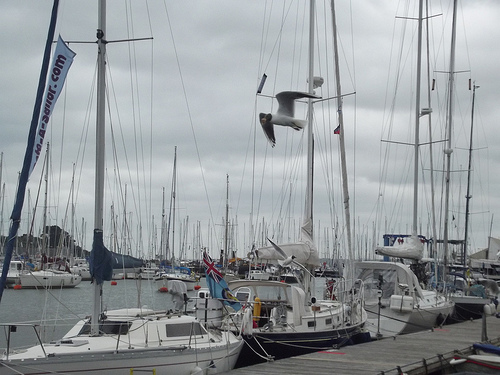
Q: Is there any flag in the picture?
A: Yes, there is a flag.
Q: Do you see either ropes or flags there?
A: Yes, there is a flag.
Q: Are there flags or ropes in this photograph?
A: Yes, there is a flag.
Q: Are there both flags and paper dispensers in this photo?
A: No, there is a flag but no paper dispensers.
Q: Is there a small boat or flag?
A: Yes, there is a small flag.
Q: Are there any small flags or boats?
A: Yes, there is a small flag.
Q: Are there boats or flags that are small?
A: Yes, the flag is small.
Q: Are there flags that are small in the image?
A: Yes, there is a small flag.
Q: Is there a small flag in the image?
A: Yes, there is a small flag.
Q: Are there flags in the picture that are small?
A: Yes, there is a flag that is small.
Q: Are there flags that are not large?
A: Yes, there is a small flag.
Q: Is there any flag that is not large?
A: Yes, there is a small flag.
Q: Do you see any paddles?
A: No, there are no paddles.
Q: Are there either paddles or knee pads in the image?
A: No, there are no paddles or knee pads.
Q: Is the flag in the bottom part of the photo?
A: Yes, the flag is in the bottom of the image.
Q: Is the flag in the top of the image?
A: No, the flag is in the bottom of the image.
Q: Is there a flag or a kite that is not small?
A: No, there is a flag but it is small.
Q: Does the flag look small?
A: Yes, the flag is small.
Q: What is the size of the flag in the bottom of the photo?
A: The flag is small.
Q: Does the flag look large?
A: No, the flag is small.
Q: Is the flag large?
A: No, the flag is small.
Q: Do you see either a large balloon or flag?
A: No, there is a flag but it is small.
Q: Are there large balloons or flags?
A: No, there is a flag but it is small.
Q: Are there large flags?
A: No, there is a flag but it is small.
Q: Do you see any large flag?
A: No, there is a flag but it is small.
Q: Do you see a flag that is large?
A: No, there is a flag but it is small.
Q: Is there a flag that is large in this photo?
A: No, there is a flag but it is small.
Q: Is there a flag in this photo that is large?
A: No, there is a flag but it is small.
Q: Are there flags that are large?
A: No, there is a flag but it is small.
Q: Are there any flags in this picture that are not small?
A: No, there is a flag but it is small.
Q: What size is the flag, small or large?
A: The flag is small.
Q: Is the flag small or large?
A: The flag is small.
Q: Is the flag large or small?
A: The flag is small.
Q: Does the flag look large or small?
A: The flag is small.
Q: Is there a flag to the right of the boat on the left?
A: Yes, there is a flag to the right of the boat.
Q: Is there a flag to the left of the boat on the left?
A: No, the flag is to the right of the boat.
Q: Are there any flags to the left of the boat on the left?
A: No, the flag is to the right of the boat.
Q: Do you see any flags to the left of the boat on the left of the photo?
A: No, the flag is to the right of the boat.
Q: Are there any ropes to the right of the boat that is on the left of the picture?
A: No, there is a flag to the right of the boat.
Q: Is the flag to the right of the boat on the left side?
A: Yes, the flag is to the right of the boat.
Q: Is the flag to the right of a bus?
A: No, the flag is to the right of the boat.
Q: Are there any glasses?
A: No, there are no glasses.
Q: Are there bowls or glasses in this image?
A: No, there are no glasses or bowls.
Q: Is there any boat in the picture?
A: Yes, there is a boat.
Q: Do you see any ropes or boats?
A: Yes, there is a boat.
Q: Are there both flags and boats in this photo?
A: Yes, there are both a boat and a flag.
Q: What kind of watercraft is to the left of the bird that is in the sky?
A: The watercraft is a boat.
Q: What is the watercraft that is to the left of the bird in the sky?
A: The watercraft is a boat.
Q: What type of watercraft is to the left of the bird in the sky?
A: The watercraft is a boat.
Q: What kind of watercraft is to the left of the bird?
A: The watercraft is a boat.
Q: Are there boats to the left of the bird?
A: Yes, there is a boat to the left of the bird.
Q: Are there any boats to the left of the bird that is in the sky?
A: Yes, there is a boat to the left of the bird.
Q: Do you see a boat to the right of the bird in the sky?
A: No, the boat is to the left of the bird.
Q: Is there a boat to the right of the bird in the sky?
A: No, the boat is to the left of the bird.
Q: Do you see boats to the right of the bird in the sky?
A: No, the boat is to the left of the bird.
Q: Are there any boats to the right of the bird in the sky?
A: No, the boat is to the left of the bird.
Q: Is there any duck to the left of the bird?
A: No, there is a boat to the left of the bird.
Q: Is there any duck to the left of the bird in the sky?
A: No, there is a boat to the left of the bird.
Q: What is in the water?
A: The boat is in the water.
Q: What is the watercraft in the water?
A: The watercraft is a boat.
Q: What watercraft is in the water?
A: The watercraft is a boat.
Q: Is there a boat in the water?
A: Yes, there is a boat in the water.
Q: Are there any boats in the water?
A: Yes, there is a boat in the water.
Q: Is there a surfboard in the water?
A: No, there is a boat in the water.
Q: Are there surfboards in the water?
A: No, there is a boat in the water.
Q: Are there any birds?
A: Yes, there is a bird.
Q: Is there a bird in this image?
A: Yes, there is a bird.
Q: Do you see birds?
A: Yes, there is a bird.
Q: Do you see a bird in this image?
A: Yes, there is a bird.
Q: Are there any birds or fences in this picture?
A: Yes, there is a bird.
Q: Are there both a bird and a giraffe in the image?
A: No, there is a bird but no giraffes.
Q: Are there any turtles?
A: No, there are no turtles.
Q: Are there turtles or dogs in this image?
A: No, there are no turtles or dogs.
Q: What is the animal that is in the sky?
A: The animal is a bird.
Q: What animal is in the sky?
A: The animal is a bird.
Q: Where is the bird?
A: The bird is in the sky.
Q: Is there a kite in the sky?
A: No, there is a bird in the sky.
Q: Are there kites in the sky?
A: No, there is a bird in the sky.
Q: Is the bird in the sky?
A: Yes, the bird is in the sky.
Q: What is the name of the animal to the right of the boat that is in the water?
A: The animal is a bird.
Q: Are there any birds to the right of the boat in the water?
A: Yes, there is a bird to the right of the boat.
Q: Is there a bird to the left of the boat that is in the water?
A: No, the bird is to the right of the boat.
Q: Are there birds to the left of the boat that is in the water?
A: No, the bird is to the right of the boat.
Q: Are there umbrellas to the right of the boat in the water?
A: No, there is a bird to the right of the boat.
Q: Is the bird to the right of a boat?
A: Yes, the bird is to the right of a boat.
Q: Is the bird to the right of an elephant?
A: No, the bird is to the right of a boat.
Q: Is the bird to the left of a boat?
A: No, the bird is to the right of a boat.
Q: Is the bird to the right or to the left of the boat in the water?
A: The bird is to the right of the boat.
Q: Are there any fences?
A: Yes, there is a fence.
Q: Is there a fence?
A: Yes, there is a fence.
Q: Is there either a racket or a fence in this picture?
A: Yes, there is a fence.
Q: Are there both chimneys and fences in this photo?
A: No, there is a fence but no chimneys.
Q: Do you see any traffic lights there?
A: No, there are no traffic lights.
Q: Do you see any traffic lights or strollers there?
A: No, there are no traffic lights or strollers.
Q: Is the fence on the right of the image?
A: Yes, the fence is on the right of the image.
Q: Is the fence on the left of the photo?
A: No, the fence is on the right of the image.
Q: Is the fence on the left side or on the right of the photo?
A: The fence is on the right of the image.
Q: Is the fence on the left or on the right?
A: The fence is on the right of the image.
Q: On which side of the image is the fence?
A: The fence is on the right of the image.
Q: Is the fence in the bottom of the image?
A: Yes, the fence is in the bottom of the image.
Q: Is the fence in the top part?
A: No, the fence is in the bottom of the image.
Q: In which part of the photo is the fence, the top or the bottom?
A: The fence is in the bottom of the image.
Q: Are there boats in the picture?
A: Yes, there is a boat.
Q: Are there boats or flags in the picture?
A: Yes, there is a boat.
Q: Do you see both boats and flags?
A: Yes, there are both a boat and a flag.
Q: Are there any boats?
A: Yes, there is a boat.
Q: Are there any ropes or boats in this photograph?
A: Yes, there is a boat.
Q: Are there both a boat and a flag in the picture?
A: Yes, there are both a boat and a flag.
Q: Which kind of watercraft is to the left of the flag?
A: The watercraft is a boat.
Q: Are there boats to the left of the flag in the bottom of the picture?
A: Yes, there is a boat to the left of the flag.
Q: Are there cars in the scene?
A: No, there are no cars.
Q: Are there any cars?
A: No, there are no cars.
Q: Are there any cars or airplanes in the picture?
A: No, there are no cars or airplanes.